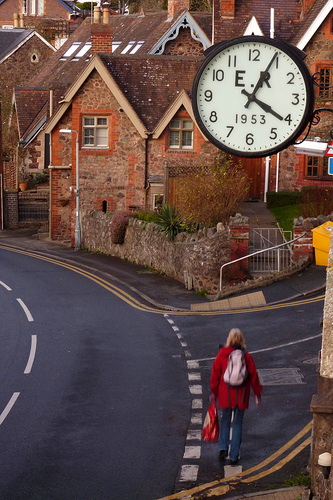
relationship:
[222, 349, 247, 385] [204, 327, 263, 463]
backpack on woman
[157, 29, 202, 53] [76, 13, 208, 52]
border under roof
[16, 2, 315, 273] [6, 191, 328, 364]
houses on hilltop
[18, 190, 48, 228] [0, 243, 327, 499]
brick steps by road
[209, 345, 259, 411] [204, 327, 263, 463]
jacket on woman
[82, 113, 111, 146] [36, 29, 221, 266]
window on house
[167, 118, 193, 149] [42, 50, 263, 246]
window on house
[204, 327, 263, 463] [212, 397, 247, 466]
woman wearing jeans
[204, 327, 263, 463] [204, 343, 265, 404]
woman wearing jacket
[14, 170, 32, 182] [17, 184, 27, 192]
plant in flowerpot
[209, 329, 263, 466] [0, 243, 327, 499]
woman crossing road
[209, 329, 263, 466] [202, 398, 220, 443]
woman has bag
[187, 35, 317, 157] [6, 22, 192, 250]
clock in front of houses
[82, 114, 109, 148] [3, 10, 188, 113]
window along roof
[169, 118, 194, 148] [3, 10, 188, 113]
window along roof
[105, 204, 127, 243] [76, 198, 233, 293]
vines leaning over wall